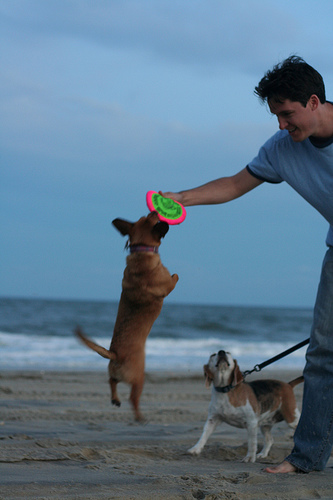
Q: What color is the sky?
A: Blue.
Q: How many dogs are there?
A: Two.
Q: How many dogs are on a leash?
A: One.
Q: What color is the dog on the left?
A: Brown.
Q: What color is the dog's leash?
A: Black.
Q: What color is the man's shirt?
A: Blue.